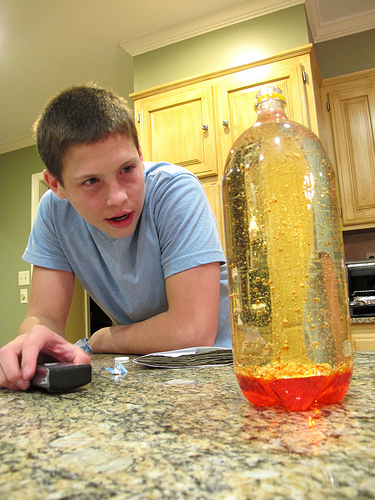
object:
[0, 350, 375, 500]
surface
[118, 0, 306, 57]
molding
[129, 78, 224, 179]
door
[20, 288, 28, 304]
sockets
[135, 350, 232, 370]
money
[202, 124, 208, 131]
knobs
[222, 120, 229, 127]
knobs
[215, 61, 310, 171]
door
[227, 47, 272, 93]
light reflection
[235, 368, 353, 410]
red liquid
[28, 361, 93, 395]
object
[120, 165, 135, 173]
eye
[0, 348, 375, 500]
counter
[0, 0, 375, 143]
ceiling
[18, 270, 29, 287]
light switch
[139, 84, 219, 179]
cabinets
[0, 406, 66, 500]
granite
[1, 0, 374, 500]
photo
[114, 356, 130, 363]
tablet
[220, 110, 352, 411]
liquid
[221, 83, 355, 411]
bottle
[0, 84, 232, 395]
boy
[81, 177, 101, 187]
eye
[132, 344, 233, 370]
envelope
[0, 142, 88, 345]
wall